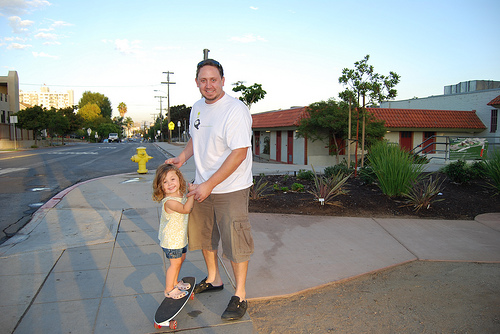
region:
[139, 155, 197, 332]
Little girl standing on skateboard.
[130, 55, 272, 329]
Man holding on to little girl on skateboard.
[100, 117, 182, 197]
Yellow fire hydrant on corner of sidewalk.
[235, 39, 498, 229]
Spike shaped plants in flowerbed.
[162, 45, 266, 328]
Man is wearing black shoes.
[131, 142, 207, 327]
Little girl is wearing sleeveless yellow shirt.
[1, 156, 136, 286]
Sidewalk slopes down into street.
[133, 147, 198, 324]
The little girl standing on skateboard.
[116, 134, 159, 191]
Yellow fire hydrant on the curb.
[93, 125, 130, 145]
A car on the road.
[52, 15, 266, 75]
The sky is sunny.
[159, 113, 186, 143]
A yellow sign in the background.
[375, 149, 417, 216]
Green plants growing in the dirt.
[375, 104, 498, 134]
The roof of the building.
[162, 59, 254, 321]
Man standing on the sidewalk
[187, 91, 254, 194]
White shirt on the man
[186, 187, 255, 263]
Shorts on the man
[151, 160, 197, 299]
Little girl standing next to the man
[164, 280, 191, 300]
Crocs shoes on the little girl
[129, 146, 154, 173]
Fire hydrant on the sidewalk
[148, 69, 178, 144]
Electric poles on the sidewalk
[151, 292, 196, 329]
Wheels of the skateboard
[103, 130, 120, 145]
Car on the road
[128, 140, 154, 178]
yellow fire hydrant on a street corner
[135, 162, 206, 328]
little girl standing on a skate board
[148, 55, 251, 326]
man holding up a little girl on a skateboad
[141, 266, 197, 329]
skateboard with red wheels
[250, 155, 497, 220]
sparse landscaping in front of a building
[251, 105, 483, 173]
red roofed building with red doors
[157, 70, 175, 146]
wooden telephone pole in the distance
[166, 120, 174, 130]
yellow crossing sign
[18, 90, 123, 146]
large trees growing on a sidewalk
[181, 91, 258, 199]
white tee shirt with a small graphic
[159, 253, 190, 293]
leg of a person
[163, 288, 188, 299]
feet of a person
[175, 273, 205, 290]
feet of a person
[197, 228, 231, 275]
leg of a person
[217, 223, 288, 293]
leg of a person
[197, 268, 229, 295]
feet of a person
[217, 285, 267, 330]
feet of a person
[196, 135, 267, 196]
arm of a person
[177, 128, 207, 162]
arm of a person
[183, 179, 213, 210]
hand of a person